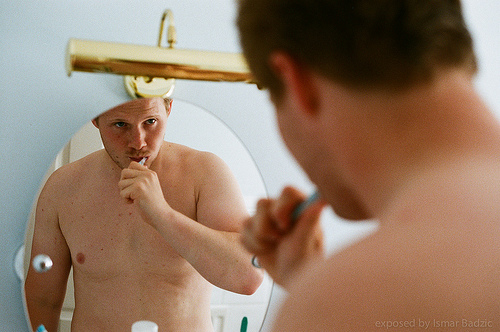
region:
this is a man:
[249, 0, 489, 304]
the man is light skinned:
[412, 121, 474, 246]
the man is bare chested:
[351, 162, 493, 312]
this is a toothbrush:
[298, 185, 320, 215]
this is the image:
[48, 107, 236, 330]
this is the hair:
[332, 19, 390, 61]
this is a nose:
[122, 133, 153, 146]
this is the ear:
[161, 99, 181, 118]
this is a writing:
[368, 311, 492, 330]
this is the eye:
[107, 115, 125, 132]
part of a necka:
[426, 145, 441, 185]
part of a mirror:
[186, 242, 187, 246]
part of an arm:
[303, 223, 310, 256]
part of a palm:
[288, 216, 289, 217]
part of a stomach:
[158, 300, 168, 314]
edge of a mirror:
[205, 143, 208, 154]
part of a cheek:
[389, 148, 399, 162]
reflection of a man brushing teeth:
[22, 97, 274, 330]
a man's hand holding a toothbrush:
[118, 156, 165, 218]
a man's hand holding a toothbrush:
[243, 178, 329, 292]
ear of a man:
[265, 48, 317, 113]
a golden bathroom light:
[60, 11, 253, 95]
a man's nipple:
[75, 249, 85, 264]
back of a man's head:
[233, 3, 488, 219]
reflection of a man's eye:
[143, 116, 157, 125]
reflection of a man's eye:
[114, 120, 126, 128]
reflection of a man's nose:
[128, 123, 148, 148]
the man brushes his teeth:
[261, 185, 321, 245]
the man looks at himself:
[105, 96, 172, 170]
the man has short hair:
[234, 0, 474, 93]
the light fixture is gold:
[66, 8, 257, 103]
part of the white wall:
[5, 2, 42, 40]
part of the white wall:
[1, 56, 49, 124]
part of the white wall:
[1, 130, 28, 187]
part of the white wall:
[237, 97, 267, 137]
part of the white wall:
[187, 3, 216, 40]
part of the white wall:
[2, 300, 19, 328]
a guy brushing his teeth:
[32, 22, 454, 312]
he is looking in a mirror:
[76, 99, 226, 262]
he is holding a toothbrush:
[241, 175, 349, 267]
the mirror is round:
[19, 96, 324, 299]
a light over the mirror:
[44, 34, 244, 86]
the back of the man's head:
[229, 10, 499, 164]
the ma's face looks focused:
[102, 106, 175, 187]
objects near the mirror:
[21, 291, 272, 331]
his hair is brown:
[224, 21, 478, 76]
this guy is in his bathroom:
[20, 12, 465, 314]